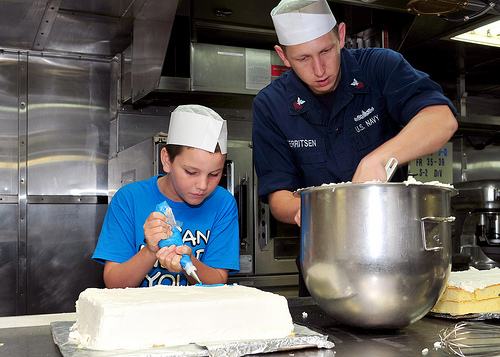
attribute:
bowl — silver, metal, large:
[294, 180, 460, 330]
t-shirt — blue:
[93, 174, 240, 288]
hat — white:
[166, 104, 228, 154]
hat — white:
[271, 1, 336, 45]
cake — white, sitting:
[71, 285, 297, 346]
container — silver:
[294, 184, 456, 332]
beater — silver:
[437, 319, 499, 355]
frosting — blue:
[84, 283, 282, 314]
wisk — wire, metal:
[440, 319, 499, 355]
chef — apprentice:
[93, 103, 237, 288]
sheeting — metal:
[2, 54, 109, 319]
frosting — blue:
[194, 283, 225, 289]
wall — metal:
[2, 53, 113, 317]